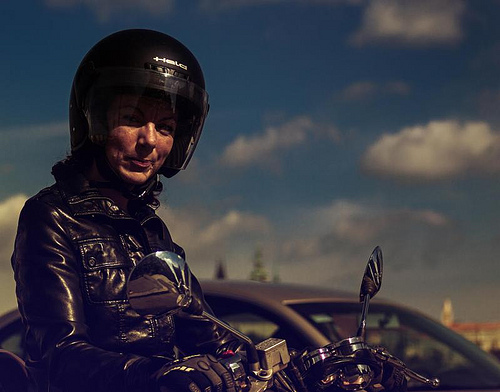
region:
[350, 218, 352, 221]
part of a cloud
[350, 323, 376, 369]
part of a handke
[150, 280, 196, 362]
part f a mirror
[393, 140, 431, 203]
part of a cloud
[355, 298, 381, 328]
part of a handle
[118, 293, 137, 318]
edge of a mirror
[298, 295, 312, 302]
edge of a car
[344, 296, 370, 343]
part of a hadke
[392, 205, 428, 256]
part of a cloud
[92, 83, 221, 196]
the head of a woman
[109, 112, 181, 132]
the eyes of a woman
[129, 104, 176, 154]
the nose of a woman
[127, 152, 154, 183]
the lips of a woman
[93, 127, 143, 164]
the cheek of a woman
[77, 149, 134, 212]
the neck of a woman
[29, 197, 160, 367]
the arm of a woman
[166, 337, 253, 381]
the hand of a woman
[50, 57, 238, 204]
a woman wearing a helmet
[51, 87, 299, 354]
a woman on a bike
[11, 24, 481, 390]
Woman looking at camera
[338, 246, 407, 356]
Black rear view mirror on bike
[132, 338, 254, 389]
Black glove on bike rider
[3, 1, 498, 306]
White clouds in the sky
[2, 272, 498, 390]
Small grey car on the road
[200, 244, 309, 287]
A few small green trees in the distance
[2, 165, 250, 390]
Black leather jacket on woman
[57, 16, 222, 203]
Black helmet on woman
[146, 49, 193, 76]
White logo on black helmet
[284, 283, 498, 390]
Clear windshield on car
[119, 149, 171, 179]
the lips of a woman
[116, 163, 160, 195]
the lips of a woman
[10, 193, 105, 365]
the arm of a woman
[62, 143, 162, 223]
the neck of a woman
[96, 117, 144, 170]
the cheeks of a woman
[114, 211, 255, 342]
the mirror on a bike